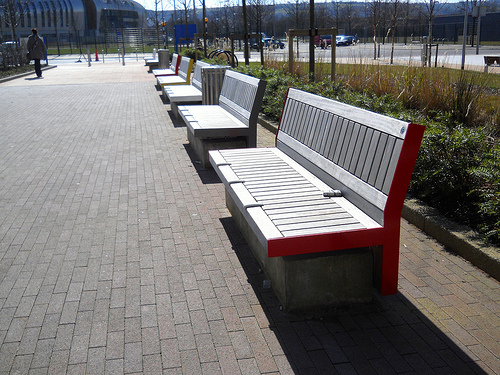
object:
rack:
[207, 49, 238, 67]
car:
[242, 32, 285, 49]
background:
[0, 0, 500, 70]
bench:
[206, 87, 425, 311]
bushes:
[172, 46, 499, 245]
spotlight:
[205, 17, 208, 22]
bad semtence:
[80, 145, 92, 317]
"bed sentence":
[259, 110, 351, 198]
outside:
[0, 0, 500, 375]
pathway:
[1, 27, 500, 375]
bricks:
[155, 293, 177, 340]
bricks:
[176, 323, 198, 351]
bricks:
[185, 290, 204, 312]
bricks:
[107, 307, 124, 332]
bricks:
[124, 341, 143, 373]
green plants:
[396, 120, 498, 237]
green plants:
[299, 75, 379, 109]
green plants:
[234, 63, 284, 113]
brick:
[99, 136, 105, 146]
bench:
[144, 48, 156, 64]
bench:
[152, 53, 181, 78]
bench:
[164, 60, 213, 120]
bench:
[177, 69, 268, 170]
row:
[142, 48, 426, 311]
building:
[0, 0, 148, 45]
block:
[224, 181, 375, 312]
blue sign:
[174, 24, 197, 52]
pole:
[180, 38, 194, 52]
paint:
[267, 124, 426, 298]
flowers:
[372, 48, 496, 97]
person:
[26, 28, 46, 79]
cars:
[335, 35, 356, 47]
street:
[233, 14, 448, 62]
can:
[201, 65, 232, 104]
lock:
[323, 189, 342, 197]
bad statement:
[1, 3, 498, 372]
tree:
[304, 0, 316, 82]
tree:
[454, 0, 477, 71]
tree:
[410, 0, 445, 67]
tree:
[236, 0, 252, 64]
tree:
[145, 0, 172, 49]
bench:
[157, 56, 194, 90]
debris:
[263, 280, 272, 289]